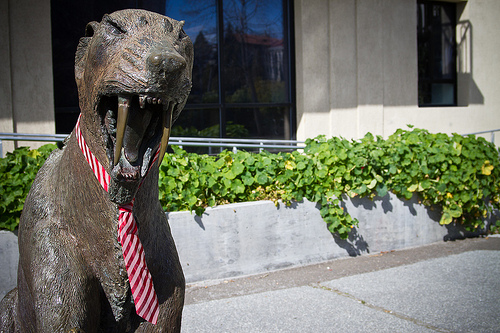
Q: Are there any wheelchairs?
A: No, there are no wheelchairs.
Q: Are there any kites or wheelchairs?
A: No, there are no wheelchairs or kites.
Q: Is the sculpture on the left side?
A: Yes, the sculpture is on the left of the image.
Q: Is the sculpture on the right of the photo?
A: No, the sculpture is on the left of the image.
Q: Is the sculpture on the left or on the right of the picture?
A: The sculpture is on the left of the image.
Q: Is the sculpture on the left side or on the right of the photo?
A: The sculpture is on the left of the image.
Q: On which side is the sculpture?
A: The sculpture is on the left of the image.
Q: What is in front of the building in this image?
A: The sculpture is in front of the building.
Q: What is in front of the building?
A: The sculpture is in front of the building.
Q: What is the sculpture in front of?
A: The sculpture is in front of the building.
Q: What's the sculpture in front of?
A: The sculpture is in front of the building.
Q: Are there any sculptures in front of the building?
A: Yes, there is a sculpture in front of the building.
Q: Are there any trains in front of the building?
A: No, there is a sculpture in front of the building.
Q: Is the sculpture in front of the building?
A: Yes, the sculpture is in front of the building.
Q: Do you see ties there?
A: Yes, there is a tie.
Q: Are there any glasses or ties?
A: Yes, there is a tie.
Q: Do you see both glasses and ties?
A: No, there is a tie but no glasses.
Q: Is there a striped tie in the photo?
A: Yes, there is a striped tie.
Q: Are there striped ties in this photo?
A: Yes, there is a striped tie.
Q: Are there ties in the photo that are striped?
A: Yes, there is a tie that is striped.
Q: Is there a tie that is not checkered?
A: Yes, there is a striped tie.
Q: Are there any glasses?
A: No, there are no glasses.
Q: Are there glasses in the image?
A: No, there are no glasses.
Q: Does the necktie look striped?
A: Yes, the necktie is striped.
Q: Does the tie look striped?
A: Yes, the tie is striped.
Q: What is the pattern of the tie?
A: The necktie is striped.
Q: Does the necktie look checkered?
A: No, the necktie is striped.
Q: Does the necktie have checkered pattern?
A: No, the necktie is striped.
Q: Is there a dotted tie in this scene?
A: No, there is a tie but it is striped.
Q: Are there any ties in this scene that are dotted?
A: No, there is a tie but it is striped.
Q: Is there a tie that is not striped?
A: No, there is a tie but it is striped.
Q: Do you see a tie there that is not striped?
A: No, there is a tie but it is striped.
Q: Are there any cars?
A: No, there are no cars.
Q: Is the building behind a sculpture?
A: Yes, the building is behind a sculpture.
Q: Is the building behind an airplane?
A: No, the building is behind a sculpture.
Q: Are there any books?
A: No, there are no books.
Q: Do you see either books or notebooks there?
A: No, there are no books or notebooks.